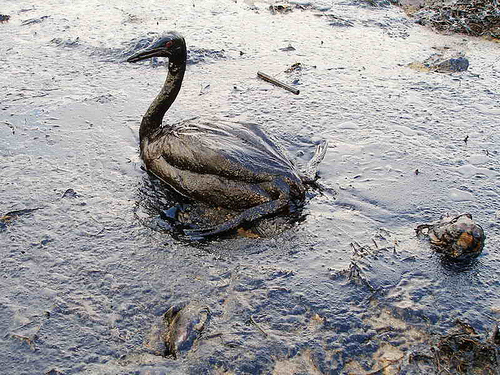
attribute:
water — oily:
[2, 6, 496, 371]